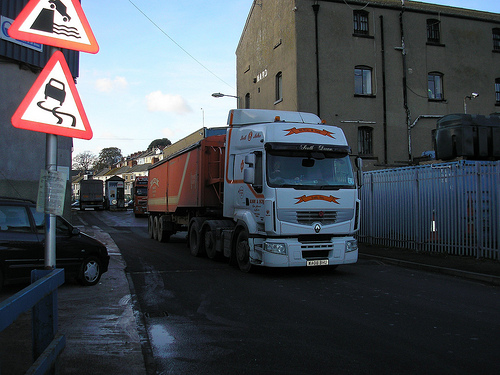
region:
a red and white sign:
[15, 49, 103, 148]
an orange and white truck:
[127, 100, 365, 295]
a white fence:
[371, 158, 485, 266]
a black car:
[10, 191, 110, 308]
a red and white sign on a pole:
[20, 48, 100, 289]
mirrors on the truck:
[243, 152, 255, 190]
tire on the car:
[81, 250, 111, 300]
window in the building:
[345, 63, 381, 103]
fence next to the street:
[370, 177, 439, 263]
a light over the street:
[206, 81, 249, 110]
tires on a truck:
[143, 203, 174, 250]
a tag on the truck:
[298, 249, 346, 273]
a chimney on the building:
[124, 148, 139, 172]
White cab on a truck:
[225, 111, 362, 266]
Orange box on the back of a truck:
[127, 137, 222, 211]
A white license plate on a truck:
[304, 257, 329, 267]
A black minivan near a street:
[2, 197, 109, 286]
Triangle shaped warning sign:
[9, 50, 93, 140]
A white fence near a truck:
[360, 161, 498, 263]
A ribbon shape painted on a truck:
[293, 193, 340, 204]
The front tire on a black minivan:
[79, 260, 101, 285]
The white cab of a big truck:
[220, 105, 361, 266]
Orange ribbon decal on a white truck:
[290, 191, 337, 201]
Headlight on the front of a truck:
[260, 235, 285, 255]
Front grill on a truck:
[295, 205, 336, 220]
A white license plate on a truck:
[303, 256, 330, 265]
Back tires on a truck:
[144, 210, 176, 240]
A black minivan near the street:
[2, 194, 108, 283]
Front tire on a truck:
[77, 252, 104, 287]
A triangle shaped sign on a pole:
[10, 51, 92, 140]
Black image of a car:
[42, 78, 69, 103]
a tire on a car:
[77, 251, 111, 292]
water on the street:
[141, 317, 179, 353]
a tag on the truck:
[299, 249, 336, 271]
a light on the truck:
[269, 231, 292, 265]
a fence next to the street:
[391, 187, 438, 259]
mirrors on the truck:
[236, 144, 262, 191]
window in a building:
[349, 61, 379, 101]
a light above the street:
[204, 77, 252, 107]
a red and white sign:
[4, 3, 99, 143]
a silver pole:
[41, 138, 65, 280]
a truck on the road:
[138, 103, 367, 285]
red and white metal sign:
[11, 49, 102, 157]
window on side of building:
[338, 2, 388, 43]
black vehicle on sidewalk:
[0, 185, 118, 296]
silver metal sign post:
[44, 126, 65, 271]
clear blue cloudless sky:
[102, 19, 153, 79]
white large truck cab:
[212, 88, 374, 298]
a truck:
[218, 110, 361, 268]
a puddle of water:
[150, 316, 173, 365]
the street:
[276, 318, 328, 358]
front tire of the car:
[81, 253, 108, 283]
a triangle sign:
[16, 53, 91, 153]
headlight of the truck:
[266, 240, 288, 255]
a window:
[351, 61, 375, 95]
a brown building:
[308, 12, 483, 120]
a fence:
[404, 168, 474, 247]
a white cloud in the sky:
[141, 86, 193, 117]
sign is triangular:
[7, 0, 100, 55]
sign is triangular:
[12, 48, 93, 140]